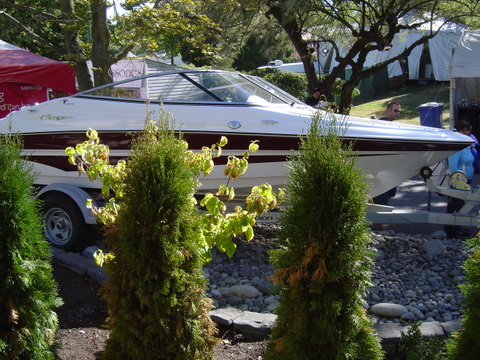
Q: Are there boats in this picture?
A: Yes, there is a boat.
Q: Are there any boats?
A: Yes, there is a boat.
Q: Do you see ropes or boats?
A: Yes, there is a boat.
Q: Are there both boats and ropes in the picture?
A: No, there is a boat but no ropes.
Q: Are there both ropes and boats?
A: No, there is a boat but no ropes.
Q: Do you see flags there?
A: No, there are no flags.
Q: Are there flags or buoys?
A: No, there are no flags or buoys.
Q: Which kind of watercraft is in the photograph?
A: The watercraft is a boat.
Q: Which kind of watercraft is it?
A: The watercraft is a boat.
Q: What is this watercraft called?
A: This is a boat.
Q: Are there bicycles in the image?
A: No, there are no bicycles.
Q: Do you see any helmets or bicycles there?
A: No, there are no bicycles or helmets.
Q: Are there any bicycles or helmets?
A: No, there are no bicycles or helmets.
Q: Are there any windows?
A: Yes, there is a window.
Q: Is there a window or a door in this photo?
A: Yes, there is a window.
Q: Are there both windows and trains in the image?
A: No, there is a window but no trains.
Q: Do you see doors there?
A: No, there are no doors.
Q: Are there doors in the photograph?
A: No, there are no doors.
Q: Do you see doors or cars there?
A: No, there are no doors or cars.